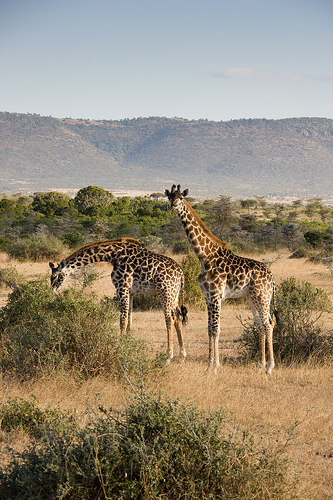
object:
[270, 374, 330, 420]
brown grass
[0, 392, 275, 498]
bushes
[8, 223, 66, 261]
bushes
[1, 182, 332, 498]
grass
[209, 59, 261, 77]
cloud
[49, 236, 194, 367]
giraffe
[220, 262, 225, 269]
spots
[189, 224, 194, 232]
spots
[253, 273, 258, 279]
spots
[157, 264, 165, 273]
spots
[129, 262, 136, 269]
spots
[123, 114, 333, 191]
hills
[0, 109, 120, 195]
hills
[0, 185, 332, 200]
horizon line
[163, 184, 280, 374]
giraffe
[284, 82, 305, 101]
white clouds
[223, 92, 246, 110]
white clouds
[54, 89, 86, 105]
white clouds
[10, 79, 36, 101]
white clouds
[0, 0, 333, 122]
blue sky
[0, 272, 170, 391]
bush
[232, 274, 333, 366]
bush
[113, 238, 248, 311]
bush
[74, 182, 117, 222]
trees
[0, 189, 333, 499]
prairie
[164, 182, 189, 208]
head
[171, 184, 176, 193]
horn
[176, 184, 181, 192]
horn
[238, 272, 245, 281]
spots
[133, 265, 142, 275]
spots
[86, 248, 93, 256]
spots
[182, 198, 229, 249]
mane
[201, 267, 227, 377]
legs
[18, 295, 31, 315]
leaves